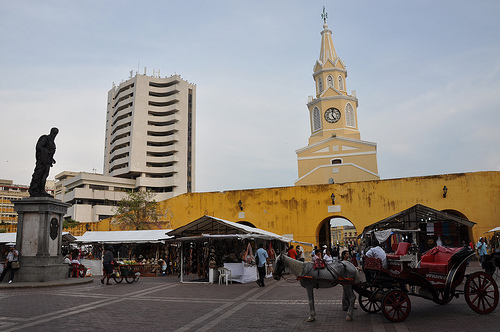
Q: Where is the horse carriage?
A: On the right.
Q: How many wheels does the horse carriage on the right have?
A: 4.